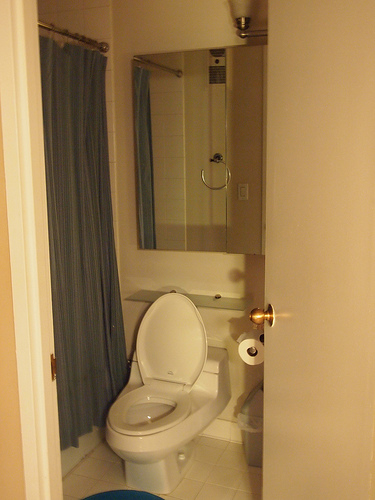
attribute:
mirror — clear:
[127, 53, 267, 258]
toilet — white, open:
[104, 290, 231, 498]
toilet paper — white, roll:
[234, 322, 266, 370]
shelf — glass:
[124, 289, 252, 314]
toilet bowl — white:
[127, 402, 174, 425]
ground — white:
[224, 124, 241, 151]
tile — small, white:
[234, 469, 262, 494]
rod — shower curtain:
[26, 25, 114, 58]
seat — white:
[110, 384, 181, 430]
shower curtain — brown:
[39, 34, 130, 453]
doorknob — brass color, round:
[246, 303, 272, 327]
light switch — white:
[237, 182, 250, 199]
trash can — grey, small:
[240, 387, 266, 467]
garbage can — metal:
[238, 378, 264, 469]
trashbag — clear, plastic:
[241, 396, 277, 437]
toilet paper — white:
[236, 334, 268, 368]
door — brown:
[249, 4, 371, 498]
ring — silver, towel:
[198, 152, 232, 189]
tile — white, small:
[62, 470, 101, 499]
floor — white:
[61, 434, 261, 497]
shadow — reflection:
[228, 267, 249, 284]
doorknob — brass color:
[243, 302, 277, 328]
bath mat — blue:
[83, 487, 164, 498]